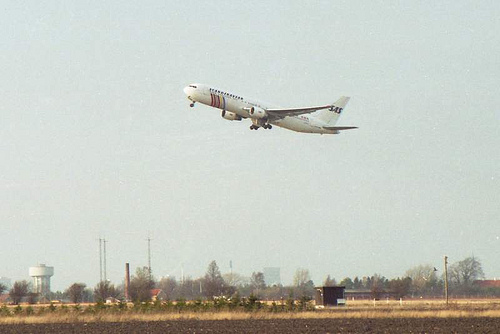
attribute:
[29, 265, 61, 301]
tower — water, in the distance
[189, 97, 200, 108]
gear — landing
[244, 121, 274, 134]
gear — rear, landing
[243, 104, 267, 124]
engine — jet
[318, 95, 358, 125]
fin — tail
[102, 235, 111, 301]
post — in distance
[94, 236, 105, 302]
post — in distance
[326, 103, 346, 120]
logo — of airline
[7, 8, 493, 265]
sky — light blue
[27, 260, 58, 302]
tower — white, water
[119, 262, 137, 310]
stack — brown, brick, smoke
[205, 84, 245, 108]
window — cocktail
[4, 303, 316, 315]
bushes — green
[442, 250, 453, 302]
pole — brown, wooden, light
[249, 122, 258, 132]
tire — black, rubber, plane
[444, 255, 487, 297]
tree — bare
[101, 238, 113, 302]
tower — wooden, electrical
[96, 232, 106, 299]
tower — wooden, electrical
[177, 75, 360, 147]
airplane — commercial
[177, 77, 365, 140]
airplane — commercial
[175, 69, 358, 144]
airplane — commercial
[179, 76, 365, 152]
airplane — commercial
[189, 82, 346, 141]
airplane — commercial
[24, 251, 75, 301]
tower — water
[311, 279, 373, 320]
building — small, brown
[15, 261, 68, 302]
tower — white, water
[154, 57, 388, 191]
airplane — a jet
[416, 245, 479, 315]
tree — large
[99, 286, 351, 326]
shrubs — green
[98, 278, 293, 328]
bushes — green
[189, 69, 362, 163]
airplane — jet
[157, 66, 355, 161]
airplane — jet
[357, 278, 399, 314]
posts — small, white, fence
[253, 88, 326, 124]
aircraft — jet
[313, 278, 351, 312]
building — small, brown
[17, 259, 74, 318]
tower — small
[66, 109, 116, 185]
sky — overcast